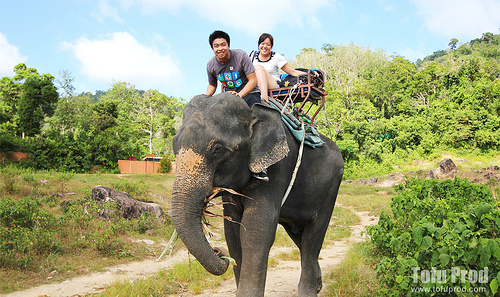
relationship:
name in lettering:
[409, 261, 491, 286] [403, 287, 490, 294]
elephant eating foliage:
[170, 92, 344, 296] [384, 184, 487, 282]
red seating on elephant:
[270, 69, 325, 129] [170, 92, 344, 296]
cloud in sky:
[67, 27, 184, 89] [15, 4, 496, 92]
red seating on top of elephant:
[267, 67, 328, 127] [173, 100, 490, 261]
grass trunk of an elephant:
[170, 149, 230, 276] [171, 99, 355, 241]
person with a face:
[246, 32, 321, 104] [251, 30, 298, 58]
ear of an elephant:
[248, 103, 288, 175] [168, 91, 344, 293]